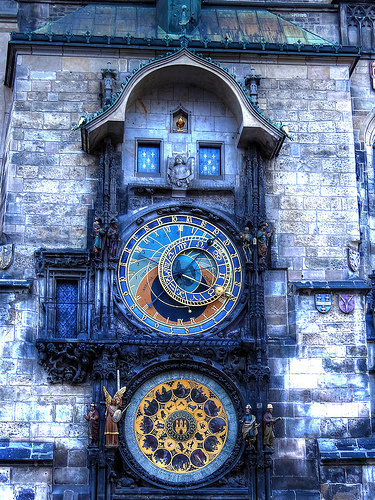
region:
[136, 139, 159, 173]
Pretty Stained glass window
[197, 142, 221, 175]
Pretty Stained glass window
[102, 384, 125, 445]
A copper angel figurine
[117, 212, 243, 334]
A very cool looking clock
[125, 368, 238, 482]
A very cool looking clock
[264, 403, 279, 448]
A man figurine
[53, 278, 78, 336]
A window in the side of a building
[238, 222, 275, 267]
Two different art figures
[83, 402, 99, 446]
A man figure next to the angel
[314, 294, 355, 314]
A couple of medieval looking crests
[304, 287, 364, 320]
the crest on the building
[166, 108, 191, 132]
gold statuette above the astronomical clock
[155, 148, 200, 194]
stone statuette above the astronomical clock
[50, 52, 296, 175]
arch above the clock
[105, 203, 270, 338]
astronomical clock on the building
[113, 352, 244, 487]
mechanical calendar on the building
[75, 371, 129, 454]
statuettes beside the mechanical calendar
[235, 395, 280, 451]
statuettes beside the mechanical calendar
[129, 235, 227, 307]
hands on the astronomical clock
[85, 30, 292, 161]
the arch has patina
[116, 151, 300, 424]
the tower has two clocks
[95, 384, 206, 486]
the clocks are colorful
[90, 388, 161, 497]
statues are by the clock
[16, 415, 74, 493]
the wall is made of brick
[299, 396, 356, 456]
light shines on the bricks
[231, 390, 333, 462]
the statues are wearing helmets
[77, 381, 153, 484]
the statues are religious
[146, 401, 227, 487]
ornaments are in the clock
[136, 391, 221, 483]
the clock is hand painted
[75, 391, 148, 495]
the statue is in the shadow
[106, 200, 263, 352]
odd clock on exterior wall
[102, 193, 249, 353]
ornate clock on exterior wall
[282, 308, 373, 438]
bricks on exterior wall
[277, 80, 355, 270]
bricks on exterior wall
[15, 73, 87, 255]
bricks on exterior wall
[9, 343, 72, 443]
bricks on exterior wall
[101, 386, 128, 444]
small winged statue on outside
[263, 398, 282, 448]
small statue of man on wall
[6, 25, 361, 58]
edge of roof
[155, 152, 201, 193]
decorative image on outside of wall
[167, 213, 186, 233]
tick of a clock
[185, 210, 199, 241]
tick of a clock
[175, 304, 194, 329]
tick of a clock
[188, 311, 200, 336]
tick of a clock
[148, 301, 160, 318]
tick of a clock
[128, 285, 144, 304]
tick of a clock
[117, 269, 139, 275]
tick of a clock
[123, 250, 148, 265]
tick of a clock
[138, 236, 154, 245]
tick of a clock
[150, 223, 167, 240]
tick of a clock